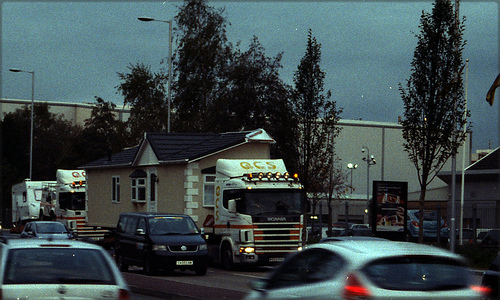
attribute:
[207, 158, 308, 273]
semi — white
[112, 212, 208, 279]
van — black, dark, charcoal color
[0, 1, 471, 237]
trees — tall, green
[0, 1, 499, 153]
sky — cloudy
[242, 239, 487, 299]
car — white, gray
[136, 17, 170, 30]
street light — on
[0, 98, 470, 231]
warehouse — large, tan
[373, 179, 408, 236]
sign — black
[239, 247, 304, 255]
headlights — on